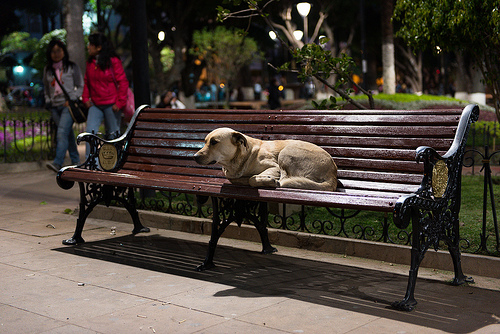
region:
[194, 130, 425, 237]
the dog is sitting on the bench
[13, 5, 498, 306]
this picture was taken at night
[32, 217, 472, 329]
a shadow of the bench is showing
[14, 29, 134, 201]
two girls are walking through the park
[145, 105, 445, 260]
the dog is all alone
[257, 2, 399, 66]
a street light is on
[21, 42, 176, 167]
the girls are holding bags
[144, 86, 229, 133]
two people are sitting down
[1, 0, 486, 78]
the park is filled with trees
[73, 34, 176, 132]
the girl is wearing a pink jacket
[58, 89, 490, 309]
Wooden park bench.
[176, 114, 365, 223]
Dog laying on bench.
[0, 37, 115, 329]
Sidewalk for pedestrian access.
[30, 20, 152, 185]
Females strolling in the park.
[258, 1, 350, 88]
Night lights for safety.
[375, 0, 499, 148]
Lush foliage.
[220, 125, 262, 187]
Dog collar for identification.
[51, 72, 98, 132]
Shoulder bag for carrying things.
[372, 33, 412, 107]
Painted tree trunks for pest reduction.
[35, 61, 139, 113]
Warm night time clothing.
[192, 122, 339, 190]
Dog resting on bench.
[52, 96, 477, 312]
Wooden bench in park.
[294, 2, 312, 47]
Light pole illuminating the night.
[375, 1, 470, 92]
Tree with white paint on trunk.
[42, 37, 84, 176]
Girl with bag strapped across.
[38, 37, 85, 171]
Girl in gray jacket.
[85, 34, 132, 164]
Girl with pink jacket.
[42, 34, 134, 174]
Two girls walking in the park at night.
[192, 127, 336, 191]
Dog staring straight ahead.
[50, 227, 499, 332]
Shadow of bench casted on sidewalk.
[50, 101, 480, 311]
a wooden bench with iron legs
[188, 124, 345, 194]
a dog is lying on the bench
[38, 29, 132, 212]
two girls are walking in the park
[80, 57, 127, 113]
a girl is wearing a red jacket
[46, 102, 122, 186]
both girls are wearing blue jeans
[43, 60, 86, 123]
the girl is wearing a purse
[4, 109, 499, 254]
a fence is behind the bench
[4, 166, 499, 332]
the pathway is cement blocks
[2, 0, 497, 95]
trees are in the park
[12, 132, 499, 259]
grassy areas are around the park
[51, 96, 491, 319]
A DOG SITTING ON A BENCH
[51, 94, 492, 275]
A METAL AND WOODEN BENCH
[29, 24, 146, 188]
TWO GIRLS WALKING TOGETHER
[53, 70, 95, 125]
A BROWN WOMAN'S HANDBAG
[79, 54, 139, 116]
A PINK LADIES JACKET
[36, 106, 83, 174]
A PAIR OF BLUE JEANS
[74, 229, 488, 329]
THE BENCHES SHADOW ON THE GROUND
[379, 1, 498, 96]
TREES IN THE BACKGROUND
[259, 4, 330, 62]
A LIGHT FIXTURE IN THE PARK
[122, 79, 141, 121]
A PINK HANDBAG